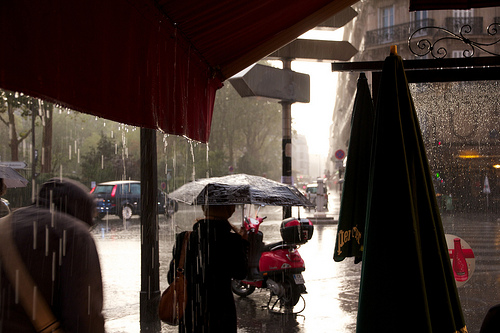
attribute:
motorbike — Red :
[248, 204, 338, 324]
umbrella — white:
[482, 174, 492, 198]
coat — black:
[164, 218, 240, 328]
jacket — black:
[167, 217, 251, 331]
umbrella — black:
[187, 152, 322, 207]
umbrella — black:
[167, 173, 316, 208]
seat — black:
[255, 241, 285, 253]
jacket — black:
[170, 220, 262, 332]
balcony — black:
[348, 7, 498, 87]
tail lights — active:
[86, 176, 118, 206]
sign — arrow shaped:
[232, 64, 312, 105]